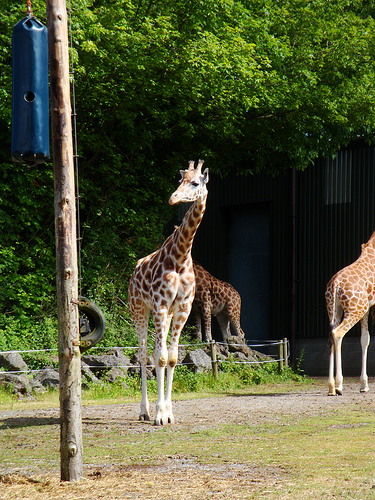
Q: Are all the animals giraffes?
A: Yes, all the animals are giraffes.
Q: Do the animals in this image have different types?
A: No, all the animals are giraffes.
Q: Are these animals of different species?
A: No, all the animals are giraffes.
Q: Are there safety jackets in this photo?
A: No, there are no safety jackets.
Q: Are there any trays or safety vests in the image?
A: No, there are no safety vests or trays.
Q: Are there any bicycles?
A: No, there are no bicycles.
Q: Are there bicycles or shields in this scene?
A: No, there are no bicycles or shields.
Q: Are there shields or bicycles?
A: No, there are no bicycles or shields.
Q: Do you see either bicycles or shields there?
A: No, there are no bicycles or shields.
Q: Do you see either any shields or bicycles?
A: No, there are no bicycles or shields.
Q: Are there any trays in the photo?
A: No, there are no trays.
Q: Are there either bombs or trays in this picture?
A: No, there are no trays or bombs.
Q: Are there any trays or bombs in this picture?
A: No, there are no trays or bombs.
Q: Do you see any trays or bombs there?
A: No, there are no trays or bombs.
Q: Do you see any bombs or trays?
A: No, there are no trays or bombs.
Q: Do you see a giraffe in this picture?
A: Yes, there is a giraffe.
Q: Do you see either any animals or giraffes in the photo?
A: Yes, there is a giraffe.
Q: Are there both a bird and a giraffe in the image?
A: No, there is a giraffe but no birds.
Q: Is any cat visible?
A: No, there are no cats.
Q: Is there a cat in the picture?
A: No, there are no cats.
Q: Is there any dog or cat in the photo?
A: No, there are no cats or dogs.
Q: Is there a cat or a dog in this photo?
A: No, there are no cats or dogs.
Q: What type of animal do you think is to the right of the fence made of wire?
A: The animal is a giraffe.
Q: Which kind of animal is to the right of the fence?
A: The animal is a giraffe.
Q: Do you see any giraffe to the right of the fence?
A: Yes, there is a giraffe to the right of the fence.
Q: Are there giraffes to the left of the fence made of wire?
A: No, the giraffe is to the right of the fence.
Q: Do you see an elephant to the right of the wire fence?
A: No, there is a giraffe to the right of the fence.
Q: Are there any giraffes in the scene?
A: Yes, there is a giraffe.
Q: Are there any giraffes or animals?
A: Yes, there is a giraffe.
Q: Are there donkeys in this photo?
A: No, there are no donkeys.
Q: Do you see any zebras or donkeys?
A: No, there are no donkeys or zebras.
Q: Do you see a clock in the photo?
A: No, there are no clocks.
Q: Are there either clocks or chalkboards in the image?
A: No, there are no clocks or chalkboards.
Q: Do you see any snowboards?
A: No, there are no snowboards.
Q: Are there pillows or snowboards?
A: No, there are no snowboards or pillows.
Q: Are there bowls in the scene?
A: No, there are no bowls.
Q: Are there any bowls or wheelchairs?
A: No, there are no bowls or wheelchairs.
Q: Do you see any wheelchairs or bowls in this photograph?
A: No, there are no bowls or wheelchairs.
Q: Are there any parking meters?
A: No, there are no parking meters.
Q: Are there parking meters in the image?
A: No, there are no parking meters.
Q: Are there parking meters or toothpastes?
A: No, there are no parking meters or toothpastes.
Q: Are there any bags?
A: Yes, there is a bag.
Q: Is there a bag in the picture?
A: Yes, there is a bag.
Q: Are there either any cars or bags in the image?
A: Yes, there is a bag.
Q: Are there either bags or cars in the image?
A: Yes, there is a bag.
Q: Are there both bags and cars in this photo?
A: No, there is a bag but no cars.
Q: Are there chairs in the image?
A: No, there are no chairs.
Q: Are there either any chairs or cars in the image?
A: No, there are no chairs or cars.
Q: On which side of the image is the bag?
A: The bag is on the left of the image.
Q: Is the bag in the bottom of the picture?
A: No, the bag is in the top of the image.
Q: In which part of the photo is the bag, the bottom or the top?
A: The bag is in the top of the image.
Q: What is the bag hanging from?
A: The bag is hanging from the pole.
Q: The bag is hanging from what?
A: The bag is hanging from the pole.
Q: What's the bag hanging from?
A: The bag is hanging from the pole.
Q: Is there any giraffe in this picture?
A: Yes, there is a giraffe.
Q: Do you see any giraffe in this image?
A: Yes, there is a giraffe.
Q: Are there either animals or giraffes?
A: Yes, there is a giraffe.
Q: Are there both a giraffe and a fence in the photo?
A: Yes, there are both a giraffe and a fence.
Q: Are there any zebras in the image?
A: No, there are no zebras.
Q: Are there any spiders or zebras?
A: No, there are no zebras or spiders.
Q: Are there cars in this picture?
A: No, there are no cars.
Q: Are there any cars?
A: No, there are no cars.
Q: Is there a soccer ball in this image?
A: No, there are no soccer balls.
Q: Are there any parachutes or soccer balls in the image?
A: No, there are no soccer balls or parachutes.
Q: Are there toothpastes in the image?
A: No, there are no toothpastes.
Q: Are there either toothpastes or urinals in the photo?
A: No, there are no toothpastes or urinals.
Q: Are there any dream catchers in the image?
A: No, there are no dream catchers.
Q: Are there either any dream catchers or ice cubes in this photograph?
A: No, there are no dream catchers or ice cubes.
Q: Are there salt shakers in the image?
A: No, there are no salt shakers.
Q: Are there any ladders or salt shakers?
A: No, there are no salt shakers or ladders.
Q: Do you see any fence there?
A: Yes, there is a fence.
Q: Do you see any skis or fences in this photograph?
A: Yes, there is a fence.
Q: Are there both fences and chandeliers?
A: No, there is a fence but no chandeliers.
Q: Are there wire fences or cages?
A: Yes, there is a wire fence.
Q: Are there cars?
A: No, there are no cars.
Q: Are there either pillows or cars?
A: No, there are no cars or pillows.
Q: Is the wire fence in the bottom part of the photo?
A: Yes, the fence is in the bottom of the image.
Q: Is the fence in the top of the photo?
A: No, the fence is in the bottom of the image.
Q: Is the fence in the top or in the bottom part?
A: The fence is in the bottom of the image.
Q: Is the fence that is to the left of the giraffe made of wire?
A: Yes, the fence is made of wire.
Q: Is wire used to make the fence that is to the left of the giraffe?
A: Yes, the fence is made of wire.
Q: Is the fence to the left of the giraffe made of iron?
A: No, the fence is made of wire.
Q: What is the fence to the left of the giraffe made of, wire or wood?
A: The fence is made of wire.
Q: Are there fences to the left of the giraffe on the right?
A: Yes, there is a fence to the left of the giraffe.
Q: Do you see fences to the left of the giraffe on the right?
A: Yes, there is a fence to the left of the giraffe.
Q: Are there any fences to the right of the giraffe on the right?
A: No, the fence is to the left of the giraffe.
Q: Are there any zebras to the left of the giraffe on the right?
A: No, there is a fence to the left of the giraffe.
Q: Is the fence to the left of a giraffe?
A: Yes, the fence is to the left of a giraffe.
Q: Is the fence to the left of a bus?
A: No, the fence is to the left of a giraffe.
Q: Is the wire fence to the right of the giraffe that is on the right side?
A: No, the fence is to the left of the giraffe.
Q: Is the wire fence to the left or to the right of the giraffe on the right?
A: The fence is to the left of the giraffe.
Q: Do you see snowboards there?
A: No, there are no snowboards.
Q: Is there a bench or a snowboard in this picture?
A: No, there are no snowboards or benches.